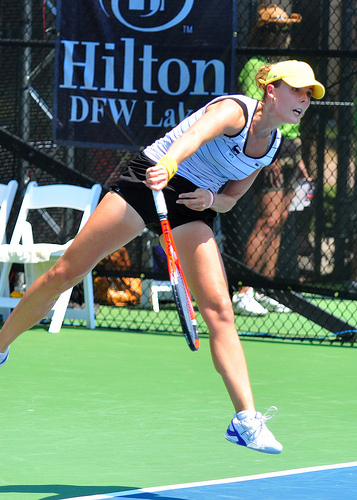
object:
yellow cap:
[248, 46, 343, 114]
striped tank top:
[139, 92, 282, 194]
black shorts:
[110, 151, 217, 237]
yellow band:
[155, 154, 178, 183]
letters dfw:
[67, 95, 138, 127]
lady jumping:
[0, 54, 328, 459]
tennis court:
[0, 279, 357, 498]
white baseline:
[64, 460, 356, 500]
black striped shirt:
[141, 93, 284, 196]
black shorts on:
[109, 149, 217, 238]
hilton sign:
[58, 35, 230, 98]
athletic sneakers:
[223, 403, 284, 456]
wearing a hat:
[252, 54, 327, 127]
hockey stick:
[151, 182, 201, 353]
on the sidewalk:
[0, 290, 357, 500]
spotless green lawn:
[0, 296, 357, 500]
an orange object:
[91, 245, 143, 309]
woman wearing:
[0, 55, 326, 456]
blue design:
[226, 418, 247, 448]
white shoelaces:
[228, 404, 279, 440]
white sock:
[235, 407, 258, 420]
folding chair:
[0, 179, 103, 336]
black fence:
[0, 2, 356, 354]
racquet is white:
[151, 181, 200, 352]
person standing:
[231, 3, 318, 319]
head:
[255, 58, 327, 126]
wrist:
[156, 155, 178, 181]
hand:
[142, 159, 171, 193]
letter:
[58, 38, 101, 92]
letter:
[99, 40, 119, 93]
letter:
[118, 36, 139, 94]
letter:
[137, 43, 159, 95]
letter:
[157, 57, 191, 98]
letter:
[68, 94, 90, 124]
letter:
[88, 96, 108, 125]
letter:
[106, 97, 137, 127]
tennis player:
[0, 57, 327, 455]